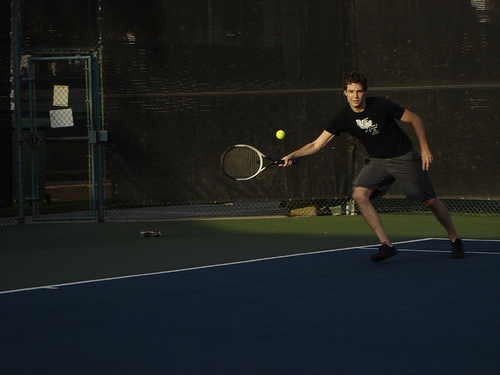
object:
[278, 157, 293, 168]
hand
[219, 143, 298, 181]
racket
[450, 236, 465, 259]
sneakers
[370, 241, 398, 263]
shoes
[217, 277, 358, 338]
blue color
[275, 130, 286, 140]
ball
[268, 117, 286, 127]
blue sky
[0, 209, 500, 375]
court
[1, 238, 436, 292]
white line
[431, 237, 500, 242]
white line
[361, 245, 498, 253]
white line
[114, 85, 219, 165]
black pants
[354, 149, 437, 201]
shorts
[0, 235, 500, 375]
tennis court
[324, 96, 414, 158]
shirt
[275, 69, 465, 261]
man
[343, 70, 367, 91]
short hair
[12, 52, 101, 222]
door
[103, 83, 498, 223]
fence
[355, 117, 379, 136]
symbol